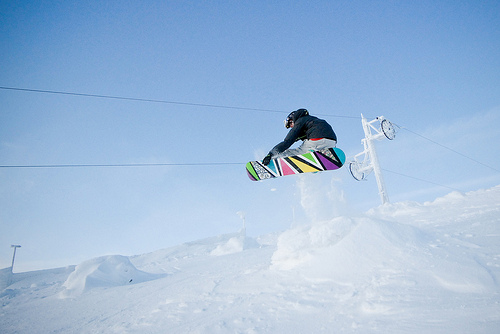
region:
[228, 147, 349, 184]
Bottom of the snowboard decorated with many colors.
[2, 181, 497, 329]
Mountainside covered in feet of snow.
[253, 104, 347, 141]
Snowboarder wearing a black jacket.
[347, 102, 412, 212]
Device used to help the lines move up and down the mountain.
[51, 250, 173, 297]
Pile of snow accumulated on the mountain.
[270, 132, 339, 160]
White snowboard pants being worn by a man.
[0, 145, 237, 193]
Cable line hanging in the air used for chair lifts.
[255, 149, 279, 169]
Black gloves being worn by a snowboarder.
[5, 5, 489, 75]
Beautiful blue sky void of any clouds.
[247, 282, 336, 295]
snow on the ground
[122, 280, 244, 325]
snow on the hill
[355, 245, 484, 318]
tracks on the snow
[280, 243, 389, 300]
the snow is white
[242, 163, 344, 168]
rainbow on the snowboard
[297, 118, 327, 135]
the coat is black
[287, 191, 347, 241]
snow in the air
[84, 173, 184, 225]
the sky is clear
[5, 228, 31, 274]
pole in the snow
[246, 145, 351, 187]
Person on a board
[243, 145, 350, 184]
Person is on a board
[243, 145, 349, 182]
Person on a snowboard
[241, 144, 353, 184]
Person is on a snowboard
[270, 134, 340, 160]
Person wearing pants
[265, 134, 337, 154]
Person wearing gray pants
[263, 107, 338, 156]
Person wearing a dark blue jacket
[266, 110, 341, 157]
Person is wearing a dark blue jacket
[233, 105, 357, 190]
A snowboarder in the air.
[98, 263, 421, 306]
Blazing white snow on the ground.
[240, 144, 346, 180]
A colorful snow board.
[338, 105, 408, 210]
Large metal apparatus in the snow.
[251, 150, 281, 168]
Man's hand on a snowboard.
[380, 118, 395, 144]
Wheel of a ski lift.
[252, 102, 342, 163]
Man wearing a jacket.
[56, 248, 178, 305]
A large snow drift.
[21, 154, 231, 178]
Metal wire in the sky.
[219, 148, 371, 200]
This is a snowboard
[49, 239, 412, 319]
The ground is made of snow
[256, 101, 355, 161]
The coat is blue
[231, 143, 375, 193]
Pink, yellow, black, green, and purple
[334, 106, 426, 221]
This is a white poll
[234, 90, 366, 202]
The person is in the air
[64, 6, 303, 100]
No clouds are in the sky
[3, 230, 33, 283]
A pole to the side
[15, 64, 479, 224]
Wires are black